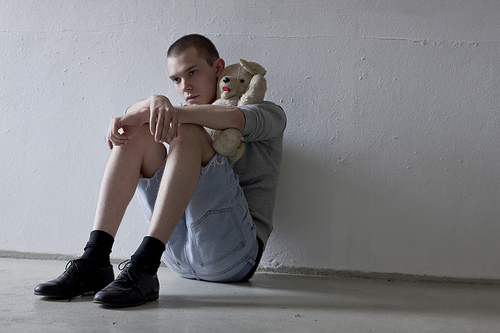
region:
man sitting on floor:
[33, 30, 275, 310]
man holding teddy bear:
[35, 32, 272, 307]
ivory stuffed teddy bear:
[197, 61, 266, 159]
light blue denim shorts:
[131, 155, 268, 282]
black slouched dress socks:
[83, 228, 169, 266]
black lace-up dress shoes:
[38, 255, 162, 310]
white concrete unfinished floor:
[1, 250, 496, 330]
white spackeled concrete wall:
[2, 1, 499, 273]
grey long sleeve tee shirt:
[237, 102, 282, 242]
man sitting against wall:
[33, 34, 287, 309]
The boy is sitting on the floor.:
[32, 25, 284, 329]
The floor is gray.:
[260, 282, 380, 330]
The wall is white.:
[292, 15, 499, 257]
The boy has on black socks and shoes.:
[41, 224, 151, 331]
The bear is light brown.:
[207, 53, 269, 160]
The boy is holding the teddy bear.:
[116, 32, 291, 183]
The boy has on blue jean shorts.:
[136, 163, 263, 279]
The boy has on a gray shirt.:
[221, 101, 279, 250]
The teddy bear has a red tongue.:
[213, 72, 250, 117]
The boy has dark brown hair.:
[152, 28, 239, 106]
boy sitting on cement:
[107, 34, 319, 312]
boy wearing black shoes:
[39, 39, 297, 313]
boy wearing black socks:
[74, 32, 307, 315]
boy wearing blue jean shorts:
[89, 22, 324, 282]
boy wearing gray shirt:
[122, 31, 304, 280]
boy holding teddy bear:
[92, 11, 296, 262]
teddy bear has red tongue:
[207, 52, 270, 153]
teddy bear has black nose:
[213, 51, 272, 186]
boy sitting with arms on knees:
[87, 24, 270, 264]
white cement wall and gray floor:
[322, 135, 482, 332]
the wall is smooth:
[297, 48, 462, 288]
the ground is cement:
[260, 282, 485, 329]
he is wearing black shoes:
[30, 222, 150, 329]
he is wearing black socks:
[40, 215, 183, 325]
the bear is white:
[205, 53, 261, 163]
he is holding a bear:
[160, 41, 310, 174]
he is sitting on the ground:
[96, 41, 312, 296]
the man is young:
[50, 26, 296, 321]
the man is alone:
[10, 8, 490, 253]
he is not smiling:
[41, 26, 287, 312]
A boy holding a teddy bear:
[33, 24, 350, 312]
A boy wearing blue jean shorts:
[23, 16, 340, 315]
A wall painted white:
[319, 18, 468, 254]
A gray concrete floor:
[286, 284, 461, 319]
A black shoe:
[90, 251, 174, 314]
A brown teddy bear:
[203, 55, 275, 107]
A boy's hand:
[141, 90, 182, 142]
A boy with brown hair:
[30, 18, 293, 314]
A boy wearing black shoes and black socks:
[27, 27, 364, 318]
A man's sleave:
[229, 97, 301, 146]